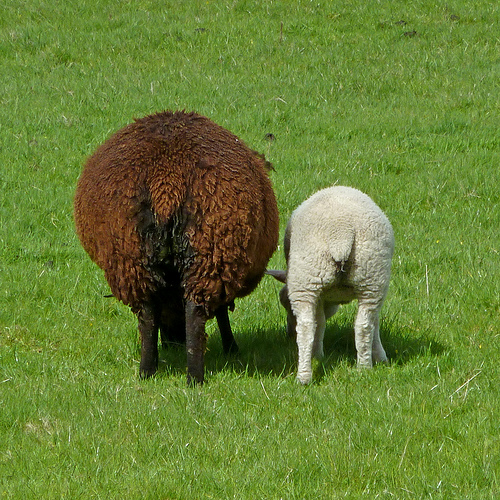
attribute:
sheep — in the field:
[269, 186, 394, 383]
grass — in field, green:
[7, 1, 494, 494]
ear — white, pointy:
[268, 253, 296, 285]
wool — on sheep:
[87, 122, 291, 307]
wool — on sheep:
[297, 204, 376, 259]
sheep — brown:
[48, 107, 270, 387]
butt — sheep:
[75, 106, 277, 307]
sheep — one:
[273, 171, 398, 378]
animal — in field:
[73, 107, 278, 384]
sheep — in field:
[287, 180, 399, 391]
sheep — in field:
[47, 98, 421, 383]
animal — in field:
[266, 182, 416, 389]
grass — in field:
[303, 65, 483, 171]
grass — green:
[202, 384, 498, 490]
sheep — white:
[273, 179, 420, 384]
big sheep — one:
[66, 91, 276, 390]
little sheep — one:
[271, 172, 408, 388]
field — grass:
[1, 0, 497, 499]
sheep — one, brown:
[64, 109, 279, 383]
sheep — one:
[278, 187, 403, 387]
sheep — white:
[258, 165, 423, 423]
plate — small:
[279, 180, 391, 392]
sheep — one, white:
[262, 183, 398, 385]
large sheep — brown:
[71, 109, 279, 388]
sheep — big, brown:
[93, 90, 250, 371]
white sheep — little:
[269, 184, 394, 384]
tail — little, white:
[318, 240, 357, 271]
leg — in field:
[137, 297, 160, 379]